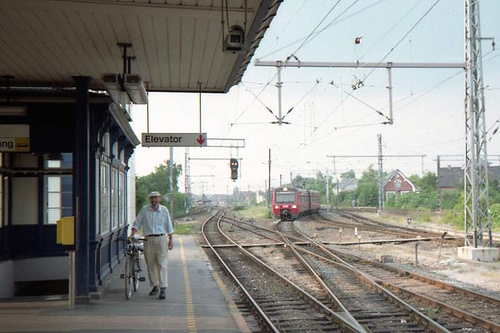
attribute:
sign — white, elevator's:
[140, 130, 211, 150]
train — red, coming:
[268, 185, 323, 220]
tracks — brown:
[201, 204, 499, 331]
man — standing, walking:
[128, 190, 179, 298]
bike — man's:
[118, 233, 144, 298]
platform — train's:
[7, 236, 247, 332]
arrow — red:
[198, 133, 206, 148]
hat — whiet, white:
[146, 187, 164, 197]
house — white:
[376, 168, 419, 205]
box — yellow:
[55, 216, 75, 249]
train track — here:
[276, 221, 432, 326]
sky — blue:
[110, 0, 500, 191]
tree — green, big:
[353, 168, 384, 207]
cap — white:
[144, 187, 163, 196]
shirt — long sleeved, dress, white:
[130, 203, 173, 241]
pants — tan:
[141, 233, 169, 288]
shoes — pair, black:
[148, 279, 163, 301]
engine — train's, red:
[269, 182, 311, 217]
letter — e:
[145, 132, 150, 143]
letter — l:
[149, 133, 156, 141]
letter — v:
[157, 133, 165, 144]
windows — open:
[9, 154, 68, 216]